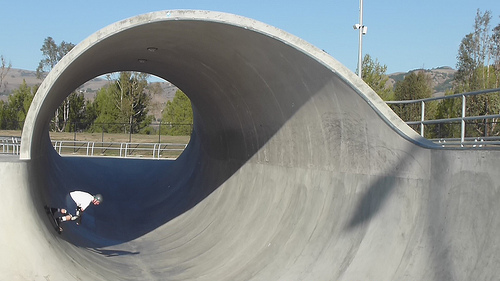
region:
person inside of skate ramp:
[46, 187, 111, 234]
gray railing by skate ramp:
[411, 97, 491, 134]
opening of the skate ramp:
[66, 66, 200, 163]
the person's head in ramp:
[95, 192, 105, 207]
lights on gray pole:
[354, 3, 366, 75]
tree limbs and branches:
[441, 7, 498, 94]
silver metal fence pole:
[463, 86, 496, 95]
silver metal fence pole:
[465, 111, 497, 121]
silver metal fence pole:
[457, 94, 466, 144]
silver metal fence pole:
[423, 91, 463, 103]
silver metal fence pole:
[421, 115, 460, 124]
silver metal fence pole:
[386, 96, 418, 106]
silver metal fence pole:
[405, 116, 422, 126]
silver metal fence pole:
[418, 100, 427, 135]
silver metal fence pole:
[151, 140, 161, 157]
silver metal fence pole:
[116, 140, 126, 155]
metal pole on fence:
[463, 83, 496, 98]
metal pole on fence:
[465, 110, 497, 124]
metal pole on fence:
[458, 93, 468, 140]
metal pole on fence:
[418, 99, 431, 139]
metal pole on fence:
[386, 98, 421, 110]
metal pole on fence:
[406, 118, 422, 128]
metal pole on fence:
[149, 139, 162, 157]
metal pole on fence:
[117, 141, 131, 156]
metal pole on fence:
[83, 141, 98, 153]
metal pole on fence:
[53, 139, 63, 154]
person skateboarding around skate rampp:
[39, 180, 106, 240]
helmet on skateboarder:
[90, 188, 105, 205]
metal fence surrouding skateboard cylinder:
[377, 84, 498, 146]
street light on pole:
[350, 1, 375, 80]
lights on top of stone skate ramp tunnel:
[130, 37, 160, 72]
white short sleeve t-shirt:
[65, 186, 95, 216]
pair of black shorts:
[57, 189, 80, 219]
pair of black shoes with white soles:
[45, 199, 65, 229]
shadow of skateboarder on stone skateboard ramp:
[79, 236, 144, 264]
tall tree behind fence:
[455, 3, 497, 138]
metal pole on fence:
[422, 91, 459, 103]